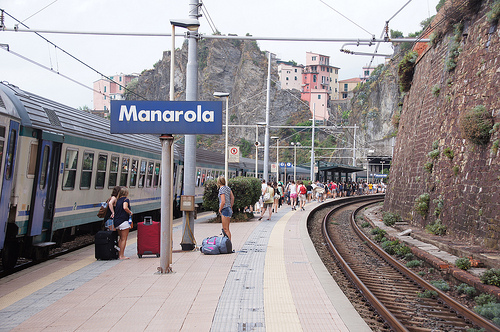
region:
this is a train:
[1, 110, 87, 236]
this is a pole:
[153, 145, 182, 205]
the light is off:
[172, 14, 201, 38]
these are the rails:
[363, 252, 431, 307]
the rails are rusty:
[363, 256, 424, 312]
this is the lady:
[212, 175, 240, 223]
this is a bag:
[199, 229, 231, 254]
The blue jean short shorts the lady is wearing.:
[220, 205, 231, 215]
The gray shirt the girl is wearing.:
[217, 185, 229, 208]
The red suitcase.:
[130, 213, 164, 259]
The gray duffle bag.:
[192, 233, 233, 253]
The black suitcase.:
[95, 230, 121, 262]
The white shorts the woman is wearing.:
[110, 220, 126, 231]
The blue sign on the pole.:
[110, 102, 223, 133]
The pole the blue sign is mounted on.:
[156, 132, 176, 273]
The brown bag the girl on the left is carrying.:
[100, 196, 115, 216]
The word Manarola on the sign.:
[109, 102, 217, 130]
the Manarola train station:
[16, 6, 446, 312]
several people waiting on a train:
[91, 170, 249, 270]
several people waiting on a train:
[312, 170, 357, 195]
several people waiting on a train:
[253, 170, 319, 220]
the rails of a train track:
[314, 190, 494, 330]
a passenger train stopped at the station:
[1, 76, 333, 250]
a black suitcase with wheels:
[91, 225, 121, 264]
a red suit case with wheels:
[132, 218, 168, 265]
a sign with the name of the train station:
[106, 92, 239, 145]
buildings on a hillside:
[268, 38, 353, 119]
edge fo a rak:
[346, 290, 363, 320]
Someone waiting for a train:
[211, 176, 243, 248]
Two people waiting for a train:
[93, 173, 139, 263]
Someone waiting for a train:
[289, 175, 299, 212]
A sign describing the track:
[109, 102, 231, 144]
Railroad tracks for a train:
[345, 218, 436, 327]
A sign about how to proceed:
[218, 131, 255, 174]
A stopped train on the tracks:
[26, 125, 99, 226]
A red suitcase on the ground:
[133, 198, 173, 261]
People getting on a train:
[260, 158, 359, 223]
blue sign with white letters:
[109, 101, 222, 133]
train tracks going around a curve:
[321, 192, 495, 329]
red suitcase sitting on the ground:
[137, 215, 159, 258]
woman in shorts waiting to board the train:
[215, 175, 236, 240]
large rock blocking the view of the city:
[125, 33, 397, 168]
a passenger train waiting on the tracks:
[1, 81, 309, 269]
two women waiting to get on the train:
[98, 183, 135, 261]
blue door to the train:
[30, 138, 55, 238]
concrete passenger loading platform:
[0, 196, 372, 330]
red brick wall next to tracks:
[385, 0, 499, 252]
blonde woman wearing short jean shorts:
[214, 174, 235, 244]